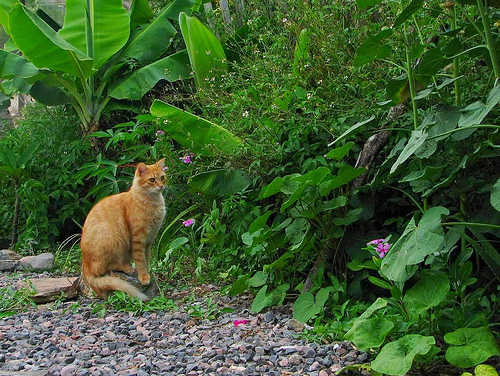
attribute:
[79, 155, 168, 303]
cat — present, motionless, brown, big, orange, hairy, little, standing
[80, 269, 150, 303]
tail — long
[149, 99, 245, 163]
leaf — broad, big, green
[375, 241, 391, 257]
flower — purple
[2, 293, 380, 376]
road — rocky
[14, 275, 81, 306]
rock — gray